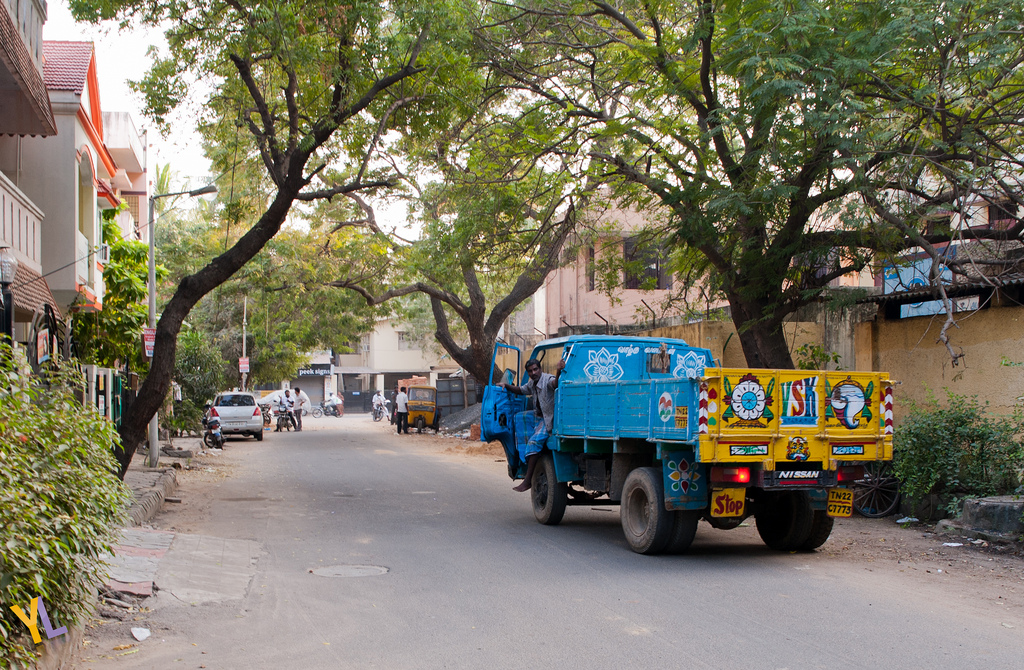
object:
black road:
[35, 383, 1023, 667]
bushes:
[9, 338, 130, 653]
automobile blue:
[474, 345, 899, 554]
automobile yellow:
[474, 345, 899, 554]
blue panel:
[559, 371, 720, 432]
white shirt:
[388, 383, 415, 431]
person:
[388, 383, 415, 431]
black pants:
[389, 402, 421, 431]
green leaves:
[632, 52, 964, 304]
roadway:
[462, 320, 906, 561]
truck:
[474, 333, 929, 518]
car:
[198, 374, 278, 438]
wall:
[332, 28, 505, 209]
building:
[332, 28, 505, 209]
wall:
[865, 290, 1018, 408]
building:
[865, 290, 1018, 408]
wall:
[16, 128, 112, 306]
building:
[16, 128, 112, 306]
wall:
[510, 220, 704, 356]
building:
[510, 220, 704, 356]